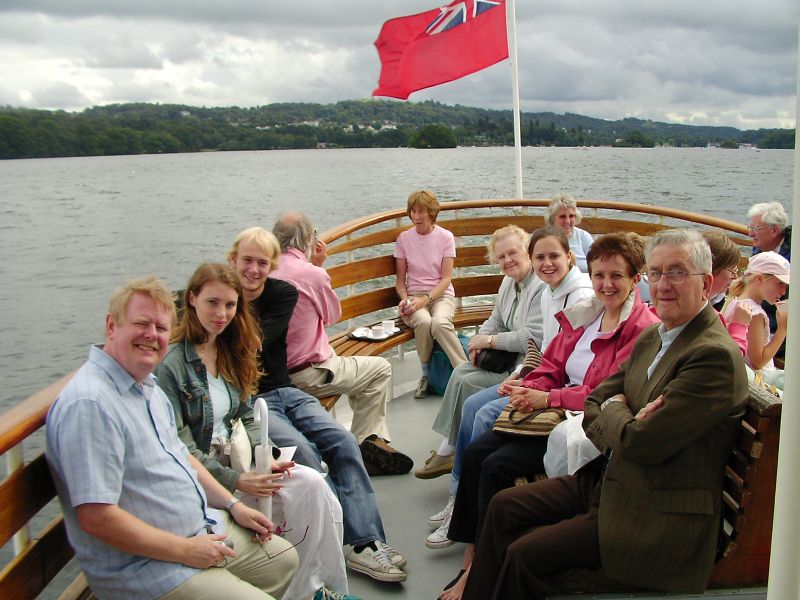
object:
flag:
[373, 0, 508, 100]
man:
[42, 278, 300, 600]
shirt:
[44, 342, 218, 600]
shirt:
[393, 224, 456, 296]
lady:
[393, 189, 469, 397]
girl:
[721, 250, 790, 391]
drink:
[773, 298, 789, 313]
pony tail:
[719, 276, 747, 315]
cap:
[743, 251, 792, 286]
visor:
[766, 273, 773, 279]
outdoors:
[0, 0, 798, 246]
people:
[49, 190, 800, 600]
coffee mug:
[372, 327, 384, 337]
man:
[267, 210, 413, 474]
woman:
[153, 261, 343, 598]